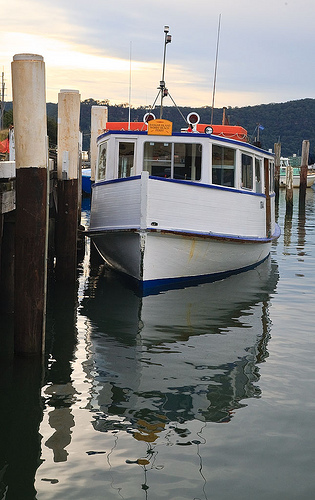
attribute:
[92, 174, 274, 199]
trim — blue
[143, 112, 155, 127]
light — off, small, round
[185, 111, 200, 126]
light — off, small, round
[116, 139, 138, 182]
window — framed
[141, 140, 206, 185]
window — framed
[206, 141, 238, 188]
window — framed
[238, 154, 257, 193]
window — framed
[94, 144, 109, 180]
window — framed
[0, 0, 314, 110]
sky — dimly lit, cloudy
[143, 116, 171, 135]
sign — orange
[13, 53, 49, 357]
post — brown, cream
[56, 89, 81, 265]
post — brown, cream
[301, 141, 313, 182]
post — brown, cream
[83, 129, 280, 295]
boat — white, wooden, docked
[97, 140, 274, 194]
windows — big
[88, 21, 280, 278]
boat — blue, white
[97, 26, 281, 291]
boat — blue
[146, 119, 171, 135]
tag — yellow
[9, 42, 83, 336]
post — sturdy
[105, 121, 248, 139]
objects — orange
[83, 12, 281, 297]
boat — blue and white, blue, white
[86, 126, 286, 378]
boat — white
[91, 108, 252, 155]
rafts — orange, life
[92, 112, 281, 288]
boat — blue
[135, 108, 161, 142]
horn — round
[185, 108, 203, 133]
horn — round